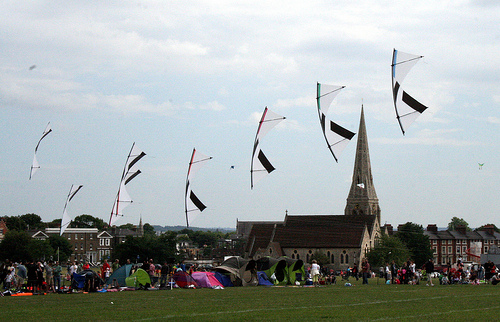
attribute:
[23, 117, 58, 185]
kite — flying, being flown, red, blac, white,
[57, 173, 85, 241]
kite — flying, being flown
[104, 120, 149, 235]
kite — being flown, flying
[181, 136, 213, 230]
kite — flying, being flown, blue, white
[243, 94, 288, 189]
kite — being flown, flying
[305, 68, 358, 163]
kite — being flown, flying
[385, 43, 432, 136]
kite — being flown, flying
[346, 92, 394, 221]
steeple — tall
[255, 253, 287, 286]
tent — green, pink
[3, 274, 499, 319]
grass — green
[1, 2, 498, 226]
sky — blue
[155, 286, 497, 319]
line — white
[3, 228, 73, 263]
leaves — green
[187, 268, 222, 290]
tent — pink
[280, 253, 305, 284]
tent — green